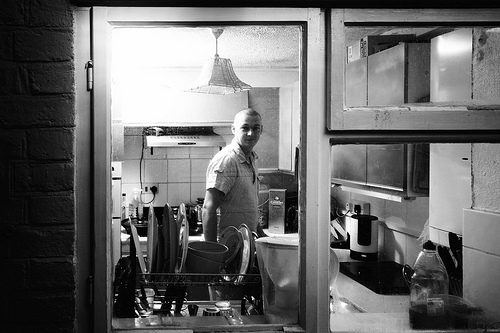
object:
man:
[191, 108, 273, 244]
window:
[99, 7, 319, 326]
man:
[196, 103, 271, 243]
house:
[1, 4, 494, 331]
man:
[188, 100, 280, 261]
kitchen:
[104, 6, 497, 321]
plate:
[141, 197, 196, 275]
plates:
[142, 205, 193, 273]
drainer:
[143, 267, 255, 309]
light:
[185, 56, 251, 97]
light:
[182, 21, 252, 97]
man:
[198, 108, 263, 240]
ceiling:
[120, 29, 303, 37]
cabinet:
[329, 8, 499, 140]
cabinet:
[306, 141, 429, 201]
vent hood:
[141, 124, 226, 151]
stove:
[141, 203, 201, 236]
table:
[329, 310, 496, 331]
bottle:
[410, 240, 452, 330]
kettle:
[344, 210, 381, 261]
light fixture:
[181, 27, 256, 97]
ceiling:
[112, 27, 304, 71]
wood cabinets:
[348, 40, 428, 205]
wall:
[2, 0, 69, 331]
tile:
[382, 200, 422, 230]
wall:
[349, 180, 445, 261]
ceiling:
[116, 31, 363, 67]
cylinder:
[347, 212, 383, 263]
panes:
[347, 32, 395, 100]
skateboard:
[395, 232, 452, 329]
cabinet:
[118, 62, 253, 124]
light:
[138, 131, 224, 148]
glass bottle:
[406, 235, 456, 329]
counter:
[108, 298, 498, 331]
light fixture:
[181, 30, 283, 108]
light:
[172, 49, 284, 108]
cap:
[423, 240, 436, 250]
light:
[183, 35, 256, 96]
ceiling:
[108, 24, 299, 70]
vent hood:
[138, 126, 230, 157]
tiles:
[166, 156, 203, 200]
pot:
[187, 240, 235, 284]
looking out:
[158, 105, 332, 282]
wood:
[335, 44, 414, 184]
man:
[195, 100, 269, 275]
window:
[85, 7, 333, 328]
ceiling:
[107, 25, 387, 73]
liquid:
[410, 300, 449, 330]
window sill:
[111, 313, 498, 331]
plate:
[174, 204, 189, 277]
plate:
[143, 204, 160, 276]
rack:
[121, 256, 262, 311]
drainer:
[104, 196, 277, 316]